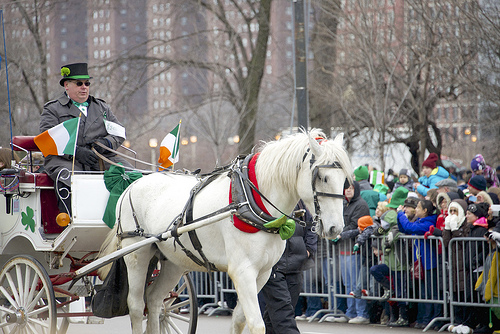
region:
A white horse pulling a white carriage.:
[0, 121, 357, 333]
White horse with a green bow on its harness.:
[94, 122, 357, 332]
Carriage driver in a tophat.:
[38, 59, 125, 222]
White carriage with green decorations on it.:
[0, 145, 234, 332]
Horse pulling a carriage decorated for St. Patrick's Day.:
[0, 60, 357, 332]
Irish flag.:
[30, 109, 85, 179]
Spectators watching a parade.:
[297, 149, 499, 332]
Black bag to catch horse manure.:
[90, 233, 139, 318]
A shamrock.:
[16, 206, 37, 234]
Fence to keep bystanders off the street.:
[175, 230, 499, 332]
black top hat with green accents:
[56, 59, 94, 85]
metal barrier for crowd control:
[316, 233, 451, 332]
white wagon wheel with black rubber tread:
[0, 251, 59, 332]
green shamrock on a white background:
[17, 203, 39, 238]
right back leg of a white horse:
[119, 237, 151, 332]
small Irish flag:
[31, 110, 86, 179]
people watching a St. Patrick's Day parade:
[1, 0, 498, 331]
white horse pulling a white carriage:
[0, 124, 360, 332]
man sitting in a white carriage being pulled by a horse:
[0, 60, 360, 332]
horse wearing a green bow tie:
[113, 124, 358, 332]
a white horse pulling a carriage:
[98, 130, 355, 331]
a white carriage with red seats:
[0, 134, 199, 332]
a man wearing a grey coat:
[40, 62, 125, 212]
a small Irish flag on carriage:
[33, 110, 80, 173]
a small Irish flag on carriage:
[158, 119, 182, 173]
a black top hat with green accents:
[60, 63, 92, 84]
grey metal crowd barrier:
[174, 232, 498, 329]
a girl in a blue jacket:
[395, 201, 441, 326]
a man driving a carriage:
[38, 64, 125, 212]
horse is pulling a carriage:
[3, 56, 358, 332]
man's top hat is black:
[54, 62, 94, 84]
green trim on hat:
[65, 71, 93, 81]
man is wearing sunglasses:
[68, 77, 92, 89]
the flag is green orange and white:
[30, 107, 85, 174]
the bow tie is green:
[99, 159, 154, 230]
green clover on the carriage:
[16, 205, 40, 233]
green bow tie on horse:
[265, 215, 297, 240]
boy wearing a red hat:
[418, 150, 440, 177]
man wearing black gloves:
[72, 134, 115, 167]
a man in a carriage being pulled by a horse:
[3, 55, 373, 292]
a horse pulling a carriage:
[111, 121, 360, 329]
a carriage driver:
[26, 51, 146, 179]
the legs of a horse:
[116, 233, 286, 330]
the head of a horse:
[281, 124, 364, 256]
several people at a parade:
[355, 160, 499, 247]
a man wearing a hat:
[28, 56, 139, 175]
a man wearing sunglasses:
[48, 58, 95, 112]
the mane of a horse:
[258, 140, 305, 197]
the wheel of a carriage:
[1, 251, 60, 331]